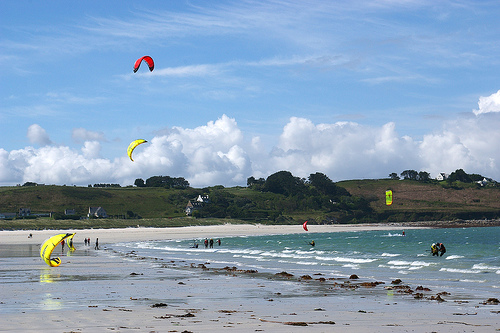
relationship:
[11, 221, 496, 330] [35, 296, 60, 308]
sand on water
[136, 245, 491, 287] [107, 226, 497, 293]
waves in water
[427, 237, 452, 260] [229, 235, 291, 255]
people standing in water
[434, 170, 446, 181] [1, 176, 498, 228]
house on hill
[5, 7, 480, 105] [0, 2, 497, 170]
thin clouds in sky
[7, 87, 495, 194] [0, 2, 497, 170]
clouds floating in sky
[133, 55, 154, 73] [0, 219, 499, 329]
kite floating over shore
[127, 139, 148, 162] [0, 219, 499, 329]
kite floating over shore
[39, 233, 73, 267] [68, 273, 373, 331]
glider resting on sand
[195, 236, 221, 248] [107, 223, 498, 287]
people standing in water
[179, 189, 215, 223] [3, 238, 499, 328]
house near water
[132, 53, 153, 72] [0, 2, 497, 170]
kite floating in sky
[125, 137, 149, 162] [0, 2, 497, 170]
kite floating in sky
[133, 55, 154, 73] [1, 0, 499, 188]
kite floating in air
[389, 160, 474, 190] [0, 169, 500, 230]
trees growing on hill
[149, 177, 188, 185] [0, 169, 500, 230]
trees growing on hill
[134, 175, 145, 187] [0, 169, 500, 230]
trees growing on hill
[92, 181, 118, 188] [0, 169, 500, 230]
trees growing on hill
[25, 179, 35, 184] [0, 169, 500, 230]
trees growing on hill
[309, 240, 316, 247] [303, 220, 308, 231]
person flying sail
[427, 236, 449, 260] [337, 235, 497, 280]
people standing in water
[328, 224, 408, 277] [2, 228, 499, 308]
wave inside water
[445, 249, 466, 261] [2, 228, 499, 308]
cap inside water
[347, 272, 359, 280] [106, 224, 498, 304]
rock visible on shoreline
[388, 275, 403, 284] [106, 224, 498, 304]
rock visible on shoreline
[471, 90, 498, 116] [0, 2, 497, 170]
cloud in sky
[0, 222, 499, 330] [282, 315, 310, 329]
beach with seaweed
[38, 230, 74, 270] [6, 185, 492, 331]
parasail on beach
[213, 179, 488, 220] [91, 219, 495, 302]
hill above beach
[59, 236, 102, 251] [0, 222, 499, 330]
people on beach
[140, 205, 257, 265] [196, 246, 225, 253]
people standing in surf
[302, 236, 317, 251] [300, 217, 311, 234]
person with sail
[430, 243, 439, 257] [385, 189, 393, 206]
people with glider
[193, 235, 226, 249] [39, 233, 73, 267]
people with glider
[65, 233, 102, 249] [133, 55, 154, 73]
people with kite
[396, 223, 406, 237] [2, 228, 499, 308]
person skiing on water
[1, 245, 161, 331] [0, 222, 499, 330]
water on beach